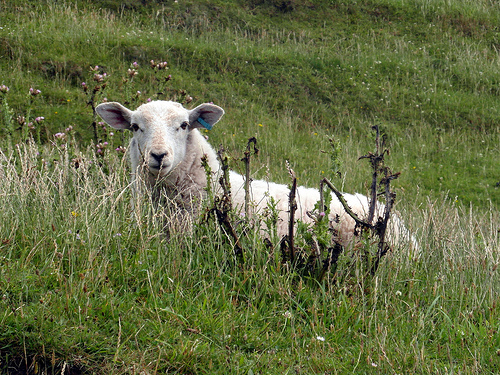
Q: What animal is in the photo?
A: A sheep.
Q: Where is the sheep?
A: In a field.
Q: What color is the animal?
A: White.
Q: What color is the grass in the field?
A: Green.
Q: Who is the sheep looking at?
A: The photographer.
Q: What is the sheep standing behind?
A: Brush and grass.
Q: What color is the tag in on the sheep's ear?
A: Blue.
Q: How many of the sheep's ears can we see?
A: Two.